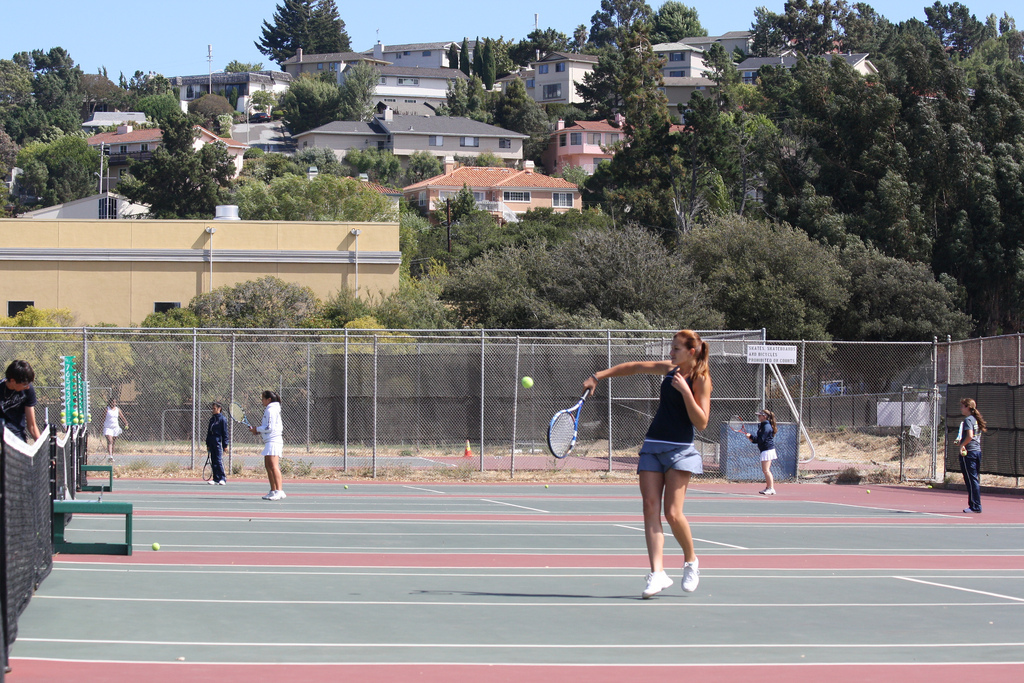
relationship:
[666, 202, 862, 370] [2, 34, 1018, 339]
tree on top of hill